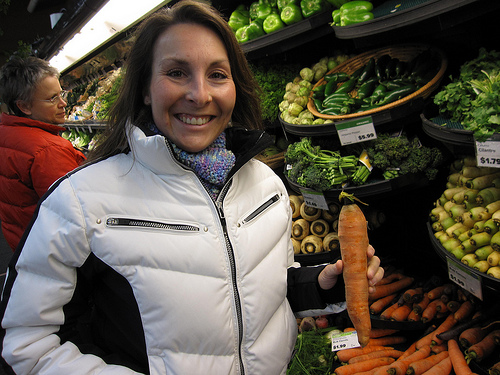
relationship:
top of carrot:
[335, 189, 361, 208] [336, 189, 374, 351]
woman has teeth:
[0, 0, 387, 374] [181, 118, 214, 125]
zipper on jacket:
[240, 193, 281, 227] [0, 119, 351, 374]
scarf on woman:
[166, 127, 237, 188] [0, 0, 387, 374]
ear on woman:
[141, 76, 153, 108] [0, 0, 387, 374]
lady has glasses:
[0, 45, 92, 254] [34, 87, 72, 104]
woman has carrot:
[0, 0, 387, 374] [336, 189, 374, 351]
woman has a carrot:
[0, 0, 387, 374] [336, 189, 374, 351]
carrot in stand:
[336, 189, 374, 351] [211, 1, 499, 374]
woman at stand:
[0, 0, 387, 374] [211, 1, 499, 374]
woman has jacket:
[0, 0, 387, 374] [0, 119, 351, 374]